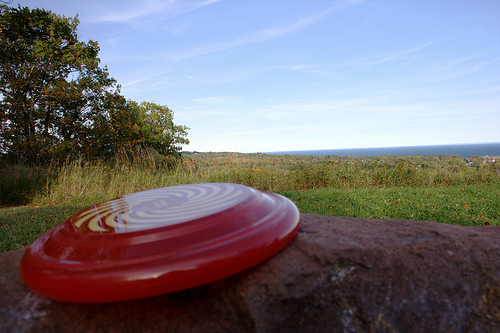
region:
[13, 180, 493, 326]
frisbee resting on flat rock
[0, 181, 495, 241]
flat green grass in front of rock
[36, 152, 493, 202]
tall green and brown grass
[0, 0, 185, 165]
tree with branches growing over grass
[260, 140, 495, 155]
wedge of gray water in distance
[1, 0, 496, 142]
blue sky with long white clouds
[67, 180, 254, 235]
gold swirls on top of frisbee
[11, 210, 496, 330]
raised texture and gray marks across rock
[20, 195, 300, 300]
circular ridges around edge of frisbee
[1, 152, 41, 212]
dark space in front of tree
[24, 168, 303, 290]
a red frisbee laying on a stone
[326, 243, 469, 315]
a red rock in a field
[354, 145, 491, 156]
calm blue water of the ocean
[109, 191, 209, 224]
yellow pattern on top of the red frisbee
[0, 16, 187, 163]
a tree growing in the field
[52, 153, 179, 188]
long green grass of the field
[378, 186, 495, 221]
several dead brown leaves on the ground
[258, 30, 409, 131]
partly cloudy blue skies over the ocean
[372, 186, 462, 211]
green grass of the hill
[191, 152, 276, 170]
several dead tan plants in the distance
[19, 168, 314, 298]
a red frisbee sitting on a rock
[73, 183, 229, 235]
yellow pattern on a red frisbee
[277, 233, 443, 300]
large red rock sitting on the ground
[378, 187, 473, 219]
green grass of the field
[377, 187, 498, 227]
many dead brown leaves on the ground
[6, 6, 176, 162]
several trees growing on a hill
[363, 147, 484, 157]
calm blue water of the ocean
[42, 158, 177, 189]
long green grass on the ground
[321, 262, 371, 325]
white spots on the rock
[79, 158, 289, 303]
Frisbee on a rock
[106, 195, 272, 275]
Red frisbee on the ground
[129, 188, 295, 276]
Frisbee on the ground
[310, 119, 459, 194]
Ocean behind the grass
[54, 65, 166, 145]
Trees near the grass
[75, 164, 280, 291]
Frisbee on the ground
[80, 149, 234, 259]
Yellow and Red Frisbee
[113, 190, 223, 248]
Yellow and Red Frisbee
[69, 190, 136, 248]
Yellow and Red Frisbee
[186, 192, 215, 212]
Yellow and Red Frisbee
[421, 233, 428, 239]
part of a rock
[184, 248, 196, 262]
part of a floater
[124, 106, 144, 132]
part of a leaf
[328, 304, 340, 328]
edge of a rock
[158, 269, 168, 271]
part of a floater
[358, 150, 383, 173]
part of the grass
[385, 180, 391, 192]
part of the plain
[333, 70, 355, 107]
part of the cloud